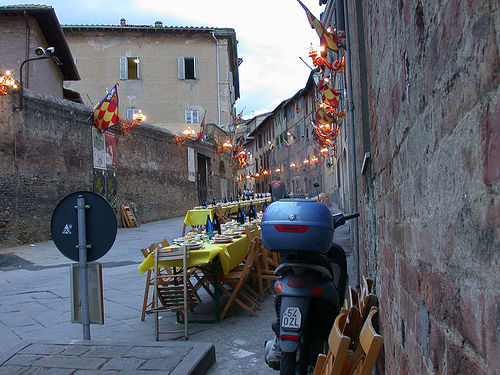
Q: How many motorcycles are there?
A: One.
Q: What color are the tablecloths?
A: Yellow.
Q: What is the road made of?
A: Brick.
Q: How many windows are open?
A: Two.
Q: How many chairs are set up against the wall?
A: Four.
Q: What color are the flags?
A: Yellow and Red.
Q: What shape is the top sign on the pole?
A: Round.